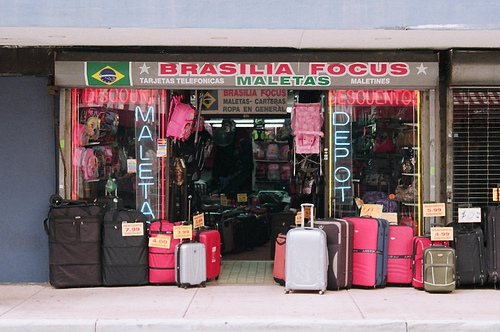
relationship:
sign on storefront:
[57, 59, 440, 87] [50, 65, 431, 288]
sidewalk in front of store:
[14, 284, 477, 331] [8, 47, 483, 330]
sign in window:
[330, 101, 367, 209] [328, 87, 420, 230]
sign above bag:
[330, 101, 367, 209] [350, 221, 391, 292]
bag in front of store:
[350, 221, 391, 292] [8, 47, 483, 330]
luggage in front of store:
[421, 249, 463, 293] [8, 47, 483, 330]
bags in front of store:
[48, 207, 148, 290] [8, 47, 483, 330]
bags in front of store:
[346, 218, 414, 286] [8, 47, 483, 330]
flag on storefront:
[84, 62, 130, 89] [50, 65, 431, 288]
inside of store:
[171, 118, 295, 205] [8, 47, 483, 330]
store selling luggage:
[8, 47, 483, 330] [283, 221, 332, 298]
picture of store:
[9, 9, 480, 331] [8, 47, 483, 330]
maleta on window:
[131, 105, 161, 212] [68, 90, 160, 208]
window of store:
[68, 90, 160, 208] [8, 47, 483, 330]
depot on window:
[330, 101, 367, 209] [328, 87, 420, 230]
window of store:
[328, 87, 420, 230] [8, 47, 483, 330]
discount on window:
[79, 87, 168, 103] [68, 90, 160, 208]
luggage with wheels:
[283, 221, 332, 298] [315, 289, 325, 296]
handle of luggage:
[296, 203, 323, 232] [283, 221, 332, 298]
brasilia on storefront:
[158, 63, 299, 80] [50, 65, 431, 288]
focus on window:
[310, 61, 404, 80] [328, 87, 420, 230]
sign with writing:
[57, 59, 440, 87] [161, 62, 412, 80]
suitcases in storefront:
[45, 201, 450, 277] [50, 65, 431, 288]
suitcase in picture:
[179, 243, 208, 287] [4, 9, 480, 331]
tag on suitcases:
[433, 225, 457, 240] [45, 201, 450, 277]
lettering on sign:
[158, 63, 403, 81] [57, 59, 440, 87]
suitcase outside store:
[307, 209, 357, 291] [8, 47, 483, 330]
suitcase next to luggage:
[446, 217, 500, 277] [417, 243, 459, 293]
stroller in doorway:
[286, 101, 317, 167] [167, 93, 315, 253]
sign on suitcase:
[449, 201, 483, 222] [446, 217, 500, 277]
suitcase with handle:
[179, 243, 208, 287] [178, 235, 207, 247]